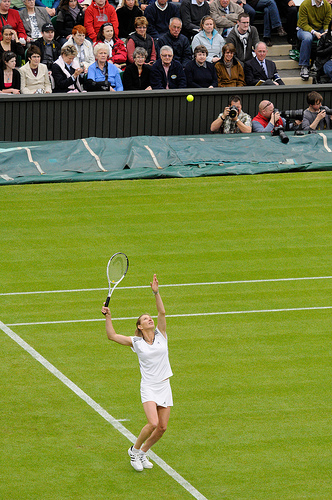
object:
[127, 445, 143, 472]
shoes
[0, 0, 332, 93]
crowd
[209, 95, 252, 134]
photographer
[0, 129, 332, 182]
tarp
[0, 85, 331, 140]
railing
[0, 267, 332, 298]
line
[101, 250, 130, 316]
racket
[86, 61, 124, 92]
shirt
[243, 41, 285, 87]
man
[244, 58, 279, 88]
suit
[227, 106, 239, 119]
camera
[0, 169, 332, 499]
grass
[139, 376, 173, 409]
skirt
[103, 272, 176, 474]
tennis player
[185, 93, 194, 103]
ball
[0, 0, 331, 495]
air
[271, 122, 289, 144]
cameras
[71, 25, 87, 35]
hair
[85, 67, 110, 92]
arm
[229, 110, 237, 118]
lens